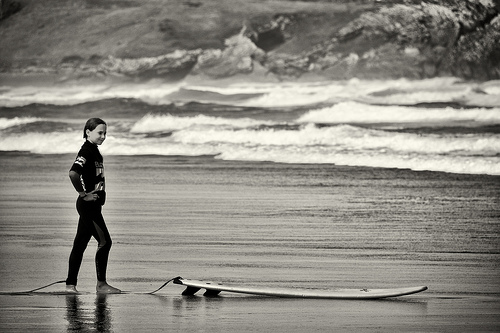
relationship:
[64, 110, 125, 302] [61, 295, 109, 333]
girl has shadow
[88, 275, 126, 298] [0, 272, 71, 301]
feet has string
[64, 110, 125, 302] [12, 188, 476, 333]
woman bare feet in sand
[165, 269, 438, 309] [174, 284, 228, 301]
surfboard has fins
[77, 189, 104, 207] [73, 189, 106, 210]
hand on hips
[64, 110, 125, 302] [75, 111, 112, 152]
girl has black hair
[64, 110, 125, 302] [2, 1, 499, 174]
girl near sea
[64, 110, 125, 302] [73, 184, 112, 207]
girl hand on t waist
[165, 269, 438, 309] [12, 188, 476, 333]
surfboard lying on sand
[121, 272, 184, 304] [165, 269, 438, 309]
rope on surfboard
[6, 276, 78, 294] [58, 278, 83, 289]
rope tied to right ankle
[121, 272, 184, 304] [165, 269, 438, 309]
rope t on surfboard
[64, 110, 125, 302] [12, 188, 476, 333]
girl on beach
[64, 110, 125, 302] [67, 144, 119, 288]
girl wears wetsuit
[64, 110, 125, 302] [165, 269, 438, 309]
girl tethered to surfboard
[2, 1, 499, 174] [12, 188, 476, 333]
waves coming into shore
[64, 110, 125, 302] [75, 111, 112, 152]
girl has brown hair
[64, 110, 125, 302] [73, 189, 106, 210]
surfer hands on hips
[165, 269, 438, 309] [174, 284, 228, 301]
surfboard has two skegs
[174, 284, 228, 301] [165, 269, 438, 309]
skegs at surfboard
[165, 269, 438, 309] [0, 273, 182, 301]
surfboard tethered on back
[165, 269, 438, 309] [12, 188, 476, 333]
surfboard on sand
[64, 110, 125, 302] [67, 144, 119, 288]
girl wears wet suit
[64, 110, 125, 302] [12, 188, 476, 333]
kid stands on sand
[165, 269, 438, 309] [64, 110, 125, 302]
surfboard front of kid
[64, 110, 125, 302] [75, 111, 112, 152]
kid has short hair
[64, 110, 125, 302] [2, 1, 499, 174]
kid looking ocean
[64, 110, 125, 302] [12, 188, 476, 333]
girl stands on beach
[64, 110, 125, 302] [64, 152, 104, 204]
girl right arm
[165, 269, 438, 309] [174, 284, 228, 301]
surf board small fins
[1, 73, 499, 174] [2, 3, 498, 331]
surf in water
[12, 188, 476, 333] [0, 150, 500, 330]
sand on shore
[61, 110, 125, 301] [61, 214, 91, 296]
girl has leg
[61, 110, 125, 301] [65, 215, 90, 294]
girl has leg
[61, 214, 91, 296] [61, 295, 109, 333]
leg has reflection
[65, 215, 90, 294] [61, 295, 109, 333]
leg has reflection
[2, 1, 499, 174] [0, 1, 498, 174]
waves in sea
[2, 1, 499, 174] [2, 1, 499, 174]
waves in water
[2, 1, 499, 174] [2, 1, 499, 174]
waves in ocean